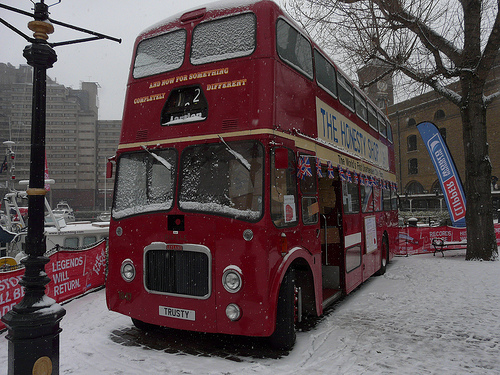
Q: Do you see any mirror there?
A: Yes, there is a mirror.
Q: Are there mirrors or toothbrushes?
A: Yes, there is a mirror.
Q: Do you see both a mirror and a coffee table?
A: No, there is a mirror but no coffee tables.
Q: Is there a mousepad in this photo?
A: No, there are no mouse pads.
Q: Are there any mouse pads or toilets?
A: No, there are no mouse pads or toilets.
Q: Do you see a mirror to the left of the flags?
A: Yes, there is a mirror to the left of the flags.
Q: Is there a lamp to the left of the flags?
A: No, there is a mirror to the left of the flags.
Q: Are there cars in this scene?
A: No, there are no cars.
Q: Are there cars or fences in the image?
A: No, there are no cars or fences.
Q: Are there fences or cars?
A: No, there are no cars or fences.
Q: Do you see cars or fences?
A: No, there are no cars or fences.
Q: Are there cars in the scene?
A: No, there are no cars.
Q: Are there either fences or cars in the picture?
A: No, there are no cars or fences.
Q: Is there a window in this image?
A: Yes, there are windows.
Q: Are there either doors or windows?
A: Yes, there are windows.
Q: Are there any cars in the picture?
A: No, there are no cars.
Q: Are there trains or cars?
A: No, there are no cars or trains.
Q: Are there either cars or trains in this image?
A: No, there are no cars or trains.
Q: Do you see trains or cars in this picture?
A: No, there are no cars or trains.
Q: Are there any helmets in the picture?
A: No, there are no helmets.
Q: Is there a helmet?
A: No, there are no helmets.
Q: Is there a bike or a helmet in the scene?
A: No, there are no helmets or bikes.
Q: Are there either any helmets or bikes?
A: No, there are no helmets or bikes.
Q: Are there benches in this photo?
A: Yes, there is a bench.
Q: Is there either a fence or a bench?
A: Yes, there is a bench.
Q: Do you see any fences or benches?
A: Yes, there is a bench.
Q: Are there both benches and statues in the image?
A: No, there is a bench but no statues.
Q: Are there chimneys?
A: No, there are no chimneys.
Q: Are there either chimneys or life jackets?
A: No, there are no chimneys or life jackets.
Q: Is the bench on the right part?
A: Yes, the bench is on the right of the image.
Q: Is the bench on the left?
A: No, the bench is on the right of the image.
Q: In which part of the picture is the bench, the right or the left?
A: The bench is on the right of the image.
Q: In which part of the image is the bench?
A: The bench is on the right of the image.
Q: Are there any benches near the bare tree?
A: Yes, there is a bench near the tree.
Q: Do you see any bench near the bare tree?
A: Yes, there is a bench near the tree.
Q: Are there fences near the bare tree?
A: No, there is a bench near the tree.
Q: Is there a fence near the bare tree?
A: No, there is a bench near the tree.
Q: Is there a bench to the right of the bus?
A: Yes, there is a bench to the right of the bus.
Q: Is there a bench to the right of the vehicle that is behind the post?
A: Yes, there is a bench to the right of the bus.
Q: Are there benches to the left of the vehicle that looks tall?
A: No, the bench is to the right of the bus.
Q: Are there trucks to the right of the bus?
A: No, there is a bench to the right of the bus.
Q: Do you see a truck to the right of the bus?
A: No, there is a bench to the right of the bus.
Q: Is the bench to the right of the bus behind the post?
A: Yes, the bench is to the right of the bus.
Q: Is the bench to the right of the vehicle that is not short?
A: Yes, the bench is to the right of the bus.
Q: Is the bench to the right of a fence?
A: No, the bench is to the right of the bus.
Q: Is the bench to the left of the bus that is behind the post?
A: No, the bench is to the right of the bus.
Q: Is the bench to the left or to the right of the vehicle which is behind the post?
A: The bench is to the right of the bus.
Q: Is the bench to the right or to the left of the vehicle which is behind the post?
A: The bench is to the right of the bus.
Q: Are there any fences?
A: No, there are no fences.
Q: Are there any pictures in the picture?
A: No, there are no pictures.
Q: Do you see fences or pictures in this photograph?
A: No, there are no pictures or fences.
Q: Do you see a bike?
A: No, there are no bikes.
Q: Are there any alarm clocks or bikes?
A: No, there are no bikes or alarm clocks.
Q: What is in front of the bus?
A: The post is in front of the bus.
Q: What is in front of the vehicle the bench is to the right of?
A: The post is in front of the bus.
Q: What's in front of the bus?
A: The post is in front of the bus.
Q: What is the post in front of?
A: The post is in front of the bus.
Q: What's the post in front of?
A: The post is in front of the bus.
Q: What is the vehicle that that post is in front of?
A: The vehicle is a bus.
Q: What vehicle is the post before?
A: The post is in front of the bus.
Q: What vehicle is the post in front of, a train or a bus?
A: The post is in front of a bus.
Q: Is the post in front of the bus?
A: Yes, the post is in front of the bus.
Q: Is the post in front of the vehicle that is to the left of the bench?
A: Yes, the post is in front of the bus.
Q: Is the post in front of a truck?
A: No, the post is in front of the bus.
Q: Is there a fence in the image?
A: No, there are no fences.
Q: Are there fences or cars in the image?
A: No, there are no fences or cars.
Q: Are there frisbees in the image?
A: No, there are no frisbees.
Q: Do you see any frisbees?
A: No, there are no frisbees.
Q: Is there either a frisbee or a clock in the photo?
A: No, there are no frisbees or clocks.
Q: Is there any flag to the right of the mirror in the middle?
A: Yes, there are flags to the right of the mirror.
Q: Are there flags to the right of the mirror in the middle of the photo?
A: Yes, there are flags to the right of the mirror.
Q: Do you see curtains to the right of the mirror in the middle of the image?
A: No, there are flags to the right of the mirror.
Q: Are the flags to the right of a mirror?
A: Yes, the flags are to the right of a mirror.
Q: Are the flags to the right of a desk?
A: No, the flags are to the right of a mirror.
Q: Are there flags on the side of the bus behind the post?
A: Yes, there are flags on the side of the bus.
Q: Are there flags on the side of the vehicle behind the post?
A: Yes, there are flags on the side of the bus.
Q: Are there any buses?
A: Yes, there is a bus.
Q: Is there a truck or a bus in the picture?
A: Yes, there is a bus.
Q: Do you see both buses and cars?
A: No, there is a bus but no cars.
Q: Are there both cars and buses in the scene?
A: No, there is a bus but no cars.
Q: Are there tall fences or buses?
A: Yes, there is a tall bus.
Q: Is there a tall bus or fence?
A: Yes, there is a tall bus.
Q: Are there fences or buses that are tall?
A: Yes, the bus is tall.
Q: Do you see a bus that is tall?
A: Yes, there is a tall bus.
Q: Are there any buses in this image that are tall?
A: Yes, there is a bus that is tall.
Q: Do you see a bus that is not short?
A: Yes, there is a tall bus.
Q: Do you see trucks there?
A: No, there are no trucks.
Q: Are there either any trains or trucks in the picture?
A: No, there are no trucks or trains.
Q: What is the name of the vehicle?
A: The vehicle is a bus.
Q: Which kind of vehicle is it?
A: The vehicle is a bus.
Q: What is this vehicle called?
A: This is a bus.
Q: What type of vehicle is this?
A: This is a bus.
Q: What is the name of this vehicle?
A: This is a bus.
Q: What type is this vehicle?
A: This is a bus.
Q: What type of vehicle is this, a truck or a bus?
A: This is a bus.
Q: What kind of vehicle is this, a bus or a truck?
A: This is a bus.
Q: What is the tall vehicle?
A: The vehicle is a bus.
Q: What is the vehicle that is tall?
A: The vehicle is a bus.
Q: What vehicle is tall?
A: The vehicle is a bus.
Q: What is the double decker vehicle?
A: The vehicle is a bus.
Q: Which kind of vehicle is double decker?
A: The vehicle is a bus.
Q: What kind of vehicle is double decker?
A: The vehicle is a bus.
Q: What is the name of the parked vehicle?
A: The vehicle is a bus.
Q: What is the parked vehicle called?
A: The vehicle is a bus.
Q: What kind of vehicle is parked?
A: The vehicle is a bus.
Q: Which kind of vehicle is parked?
A: The vehicle is a bus.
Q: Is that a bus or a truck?
A: That is a bus.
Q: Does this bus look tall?
A: Yes, the bus is tall.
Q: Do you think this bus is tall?
A: Yes, the bus is tall.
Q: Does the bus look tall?
A: Yes, the bus is tall.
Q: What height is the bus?
A: The bus is tall.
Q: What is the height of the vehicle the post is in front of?
A: The bus is tall.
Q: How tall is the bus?
A: The bus is tall.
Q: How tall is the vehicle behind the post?
A: The bus is tall.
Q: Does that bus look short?
A: No, the bus is tall.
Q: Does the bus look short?
A: No, the bus is tall.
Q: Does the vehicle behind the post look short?
A: No, the bus is tall.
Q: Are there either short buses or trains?
A: No, there is a bus but it is tall.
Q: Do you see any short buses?
A: No, there is a bus but it is tall.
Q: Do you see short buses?
A: No, there is a bus but it is tall.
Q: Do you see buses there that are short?
A: No, there is a bus but it is tall.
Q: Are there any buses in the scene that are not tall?
A: No, there is a bus but it is tall.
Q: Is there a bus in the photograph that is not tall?
A: No, there is a bus but it is tall.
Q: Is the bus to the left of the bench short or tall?
A: The bus is tall.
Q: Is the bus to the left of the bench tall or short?
A: The bus is tall.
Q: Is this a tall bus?
A: Yes, this is a tall bus.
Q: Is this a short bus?
A: No, this is a tall bus.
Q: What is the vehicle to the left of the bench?
A: The vehicle is a bus.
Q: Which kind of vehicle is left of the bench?
A: The vehicle is a bus.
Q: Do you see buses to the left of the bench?
A: Yes, there is a bus to the left of the bench.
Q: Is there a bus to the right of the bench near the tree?
A: No, the bus is to the left of the bench.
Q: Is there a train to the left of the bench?
A: No, there is a bus to the left of the bench.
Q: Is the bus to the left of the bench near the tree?
A: Yes, the bus is to the left of the bench.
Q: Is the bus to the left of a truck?
A: No, the bus is to the left of the bench.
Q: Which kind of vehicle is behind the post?
A: The vehicle is a bus.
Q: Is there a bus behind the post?
A: Yes, there is a bus behind the post.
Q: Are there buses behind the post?
A: Yes, there is a bus behind the post.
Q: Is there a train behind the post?
A: No, there is a bus behind the post.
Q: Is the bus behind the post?
A: Yes, the bus is behind the post.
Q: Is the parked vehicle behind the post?
A: Yes, the bus is behind the post.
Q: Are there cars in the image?
A: No, there are no cars.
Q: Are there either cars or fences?
A: No, there are no cars or fences.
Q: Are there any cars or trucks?
A: No, there are no cars or trucks.